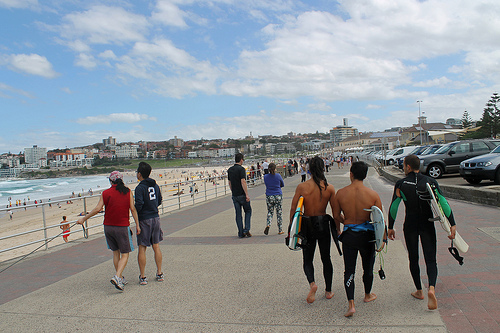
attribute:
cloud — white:
[230, 0, 498, 99]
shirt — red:
[102, 185, 133, 227]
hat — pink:
[105, 168, 125, 184]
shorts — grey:
[102, 223, 132, 257]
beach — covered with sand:
[1, 163, 281, 265]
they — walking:
[284, 154, 458, 318]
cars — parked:
[369, 138, 499, 189]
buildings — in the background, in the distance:
[0, 141, 242, 175]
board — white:
[363, 201, 386, 255]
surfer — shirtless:
[331, 159, 389, 320]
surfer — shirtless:
[286, 158, 337, 307]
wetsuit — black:
[338, 222, 378, 303]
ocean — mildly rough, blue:
[1, 178, 110, 207]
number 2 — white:
[147, 185, 159, 204]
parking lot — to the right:
[370, 137, 498, 206]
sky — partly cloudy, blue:
[1, 1, 497, 153]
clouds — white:
[1, 2, 225, 102]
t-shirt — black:
[224, 161, 246, 199]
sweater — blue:
[262, 170, 285, 197]